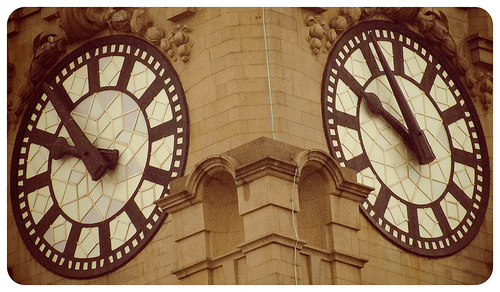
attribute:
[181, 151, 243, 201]
arch — BRICK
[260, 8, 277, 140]
cable — LONG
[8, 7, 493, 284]
wall — BRICK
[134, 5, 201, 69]
decorations — CARVED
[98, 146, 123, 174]
end — lower